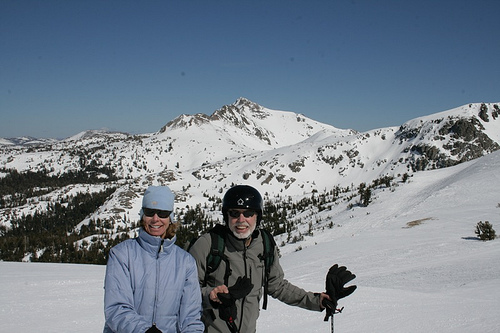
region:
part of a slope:
[411, 178, 434, 196]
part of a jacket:
[164, 272, 174, 279]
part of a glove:
[234, 290, 241, 301]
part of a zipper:
[151, 286, 173, 313]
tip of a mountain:
[251, 93, 263, 106]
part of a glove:
[338, 287, 342, 299]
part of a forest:
[66, 223, 78, 233]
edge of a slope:
[318, 152, 343, 187]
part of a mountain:
[440, 146, 449, 158]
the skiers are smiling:
[70, 172, 322, 307]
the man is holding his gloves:
[200, 263, 380, 328]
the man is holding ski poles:
[191, 271, 362, 327]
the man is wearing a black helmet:
[207, 175, 288, 259]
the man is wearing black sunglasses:
[215, 200, 282, 262]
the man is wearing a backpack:
[184, 212, 306, 329]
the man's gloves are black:
[190, 270, 348, 322]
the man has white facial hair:
[211, 200, 293, 241]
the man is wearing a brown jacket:
[191, 222, 290, 330]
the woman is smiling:
[136, 189, 184, 247]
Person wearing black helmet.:
[225, 178, 283, 216]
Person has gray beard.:
[226, 215, 280, 250]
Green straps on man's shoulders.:
[203, 219, 288, 269]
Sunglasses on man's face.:
[223, 197, 259, 222]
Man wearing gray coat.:
[214, 258, 296, 324]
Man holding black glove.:
[324, 252, 364, 324]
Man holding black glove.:
[208, 273, 273, 330]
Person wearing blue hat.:
[134, 176, 194, 235]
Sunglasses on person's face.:
[123, 190, 200, 232]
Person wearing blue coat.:
[98, 233, 205, 329]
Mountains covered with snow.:
[2, 96, 499, 263]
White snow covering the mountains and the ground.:
[0, 95, 498, 329]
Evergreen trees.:
[0, 166, 405, 267]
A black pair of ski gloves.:
[219, 264, 357, 305]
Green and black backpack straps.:
[205, 226, 277, 293]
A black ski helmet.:
[219, 182, 266, 224]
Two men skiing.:
[70, 170, 379, 331]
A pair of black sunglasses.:
[144, 208, 169, 221]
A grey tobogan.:
[137, 185, 177, 220]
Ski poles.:
[224, 301, 341, 331]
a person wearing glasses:
[141, 206, 171, 221]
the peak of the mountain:
[234, 90, 256, 108]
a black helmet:
[227, 189, 259, 209]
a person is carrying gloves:
[326, 267, 355, 303]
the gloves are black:
[231, 277, 252, 302]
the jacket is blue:
[111, 248, 201, 324]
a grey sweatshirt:
[223, 250, 264, 283]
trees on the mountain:
[7, 213, 67, 247]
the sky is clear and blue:
[36, 15, 253, 104]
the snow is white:
[379, 261, 488, 326]